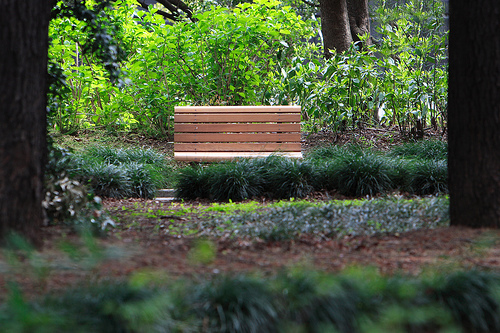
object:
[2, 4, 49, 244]
trunk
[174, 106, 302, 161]
bench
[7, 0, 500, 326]
forest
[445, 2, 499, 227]
trunk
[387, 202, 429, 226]
flowers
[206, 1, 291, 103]
plants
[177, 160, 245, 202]
plants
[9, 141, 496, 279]
ground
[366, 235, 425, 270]
dirt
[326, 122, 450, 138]
sticks.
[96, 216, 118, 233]
leaves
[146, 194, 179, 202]
steps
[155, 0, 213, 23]
branch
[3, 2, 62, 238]
tree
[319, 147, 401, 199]
bushes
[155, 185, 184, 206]
path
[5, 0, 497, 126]
background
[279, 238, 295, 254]
leaves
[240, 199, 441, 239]
grass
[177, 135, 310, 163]
seat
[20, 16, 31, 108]
lines